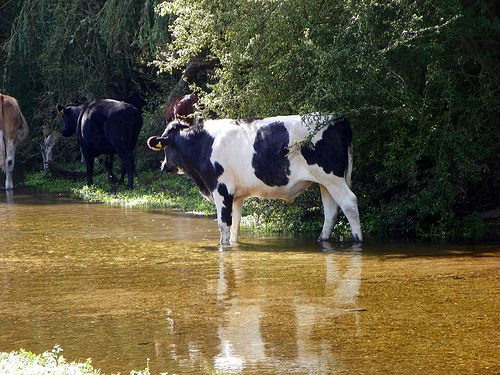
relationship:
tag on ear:
[153, 139, 164, 148] [147, 133, 172, 149]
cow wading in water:
[148, 109, 364, 248] [2, 184, 499, 373]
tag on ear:
[59, 106, 65, 115] [54, 100, 70, 116]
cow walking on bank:
[50, 98, 142, 191] [18, 158, 317, 235]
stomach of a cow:
[229, 158, 319, 202] [148, 109, 364, 248]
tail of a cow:
[343, 146, 354, 189] [138, 101, 366, 259]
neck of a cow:
[170, 123, 199, 175] [142, 117, 369, 253]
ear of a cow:
[138, 130, 174, 155] [138, 101, 366, 259]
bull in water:
[124, 105, 365, 262] [12, 206, 419, 373]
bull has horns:
[0, 91, 29, 195] [139, 130, 179, 153]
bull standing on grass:
[43, 84, 153, 195] [46, 152, 160, 195]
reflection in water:
[201, 287, 333, 371] [24, 269, 468, 357]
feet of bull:
[205, 226, 378, 254] [0, 91, 29, 195]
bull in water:
[0, 91, 29, 195] [23, 204, 478, 353]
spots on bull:
[244, 119, 356, 185] [0, 91, 29, 195]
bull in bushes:
[117, 90, 203, 125] [100, 27, 296, 142]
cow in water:
[148, 109, 364, 248] [156, 254, 351, 360]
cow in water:
[148, 109, 364, 248] [12, 238, 369, 365]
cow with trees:
[148, 109, 364, 248] [77, 3, 425, 171]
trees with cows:
[15, 20, 484, 125] [13, 90, 380, 232]